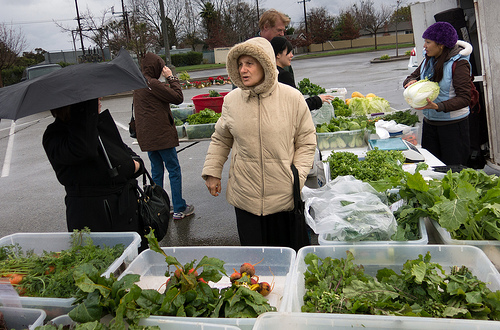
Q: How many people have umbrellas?
A: One.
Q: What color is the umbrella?
A: Black.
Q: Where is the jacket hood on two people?
A: On Heads.